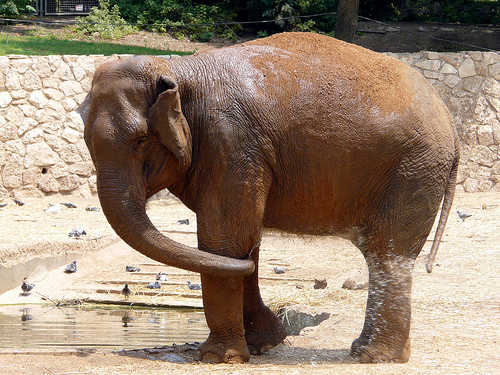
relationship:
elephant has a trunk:
[75, 31, 460, 364] [96, 169, 256, 277]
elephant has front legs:
[75, 31, 460, 364] [197, 151, 273, 333]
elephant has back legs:
[75, 31, 460, 364] [351, 227, 417, 332]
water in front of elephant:
[2, 299, 212, 374] [75, 31, 460, 364]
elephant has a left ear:
[75, 31, 460, 364] [149, 73, 195, 167]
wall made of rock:
[1, 49, 499, 207] [21, 75, 73, 179]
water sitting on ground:
[2, 299, 212, 374] [1, 184, 499, 374]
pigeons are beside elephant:
[15, 196, 203, 329] [75, 31, 460, 364]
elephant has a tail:
[75, 31, 460, 364] [423, 105, 461, 274]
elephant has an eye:
[75, 31, 460, 364] [133, 131, 147, 150]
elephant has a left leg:
[75, 31, 460, 364] [192, 156, 266, 335]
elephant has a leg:
[75, 31, 460, 364] [198, 196, 266, 333]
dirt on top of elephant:
[238, 30, 409, 113] [75, 31, 460, 364]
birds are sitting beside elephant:
[1, 192, 203, 329] [75, 31, 460, 364]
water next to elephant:
[2, 299, 212, 374] [75, 31, 460, 364]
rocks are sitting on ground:
[308, 269, 372, 299] [1, 184, 499, 374]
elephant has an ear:
[75, 31, 460, 364] [148, 77, 196, 169]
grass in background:
[1, 28, 200, 56] [2, 0, 499, 59]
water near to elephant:
[2, 299, 212, 374] [75, 31, 460, 364]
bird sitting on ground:
[65, 260, 78, 273] [1, 184, 499, 374]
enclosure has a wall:
[5, 52, 499, 374] [1, 49, 499, 207]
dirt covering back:
[238, 30, 409, 113] [176, 29, 452, 123]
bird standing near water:
[121, 283, 133, 300] [2, 299, 212, 374]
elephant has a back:
[75, 31, 460, 364] [176, 29, 452, 123]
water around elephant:
[2, 299, 212, 374] [75, 31, 460, 364]